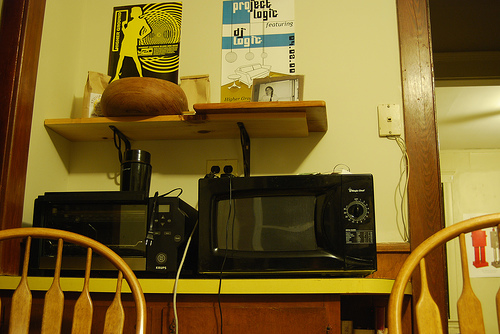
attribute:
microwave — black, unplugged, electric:
[197, 174, 377, 277]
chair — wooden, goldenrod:
[0, 227, 148, 334]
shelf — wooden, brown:
[44, 111, 310, 142]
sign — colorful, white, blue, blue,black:
[221, 1, 294, 105]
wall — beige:
[66, 1, 411, 247]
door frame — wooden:
[396, 1, 498, 333]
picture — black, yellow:
[107, 1, 182, 87]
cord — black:
[215, 171, 232, 333]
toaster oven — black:
[32, 189, 198, 276]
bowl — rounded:
[100, 76, 190, 118]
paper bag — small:
[82, 70, 111, 119]